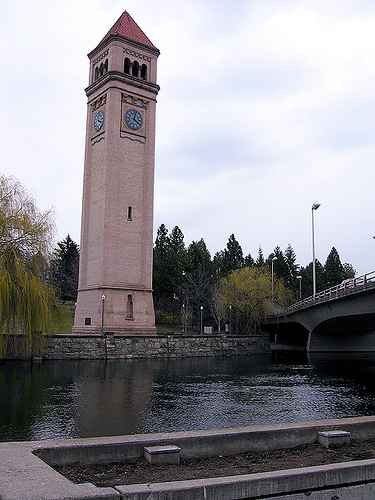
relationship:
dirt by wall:
[63, 454, 360, 488] [2, 439, 81, 492]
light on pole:
[308, 201, 322, 291] [310, 212, 319, 293]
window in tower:
[125, 203, 136, 222] [65, 8, 165, 338]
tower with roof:
[77, 6, 161, 329] [94, 8, 160, 46]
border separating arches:
[120, 95, 150, 108] [123, 57, 153, 80]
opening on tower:
[125, 199, 135, 224] [65, 8, 165, 338]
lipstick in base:
[121, 290, 135, 328] [71, 282, 160, 330]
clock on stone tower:
[125, 110, 144, 131] [73, 11, 159, 332]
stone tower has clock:
[73, 11, 159, 332] [125, 110, 144, 131]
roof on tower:
[87, 9, 159, 58] [65, 8, 165, 338]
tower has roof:
[65, 8, 165, 338] [87, 9, 159, 58]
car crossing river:
[337, 275, 362, 289] [0, 351, 363, 443]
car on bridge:
[337, 275, 362, 289] [268, 275, 361, 354]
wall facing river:
[1, 331, 273, 358] [0, 351, 363, 443]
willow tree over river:
[0, 170, 71, 364] [0, 351, 363, 443]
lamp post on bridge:
[310, 201, 323, 295] [262, 268, 373, 321]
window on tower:
[126, 203, 151, 245] [65, 8, 165, 338]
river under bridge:
[0, 346, 372, 439] [262, 268, 373, 321]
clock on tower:
[123, 107, 144, 130] [65, 8, 165, 338]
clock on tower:
[90, 110, 107, 132] [65, 8, 165, 338]